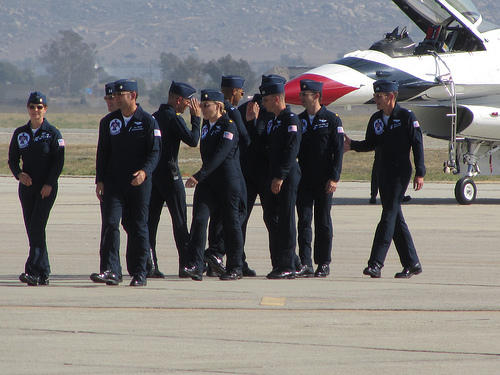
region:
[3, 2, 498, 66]
hazy over rocky terrain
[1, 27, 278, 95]
trees in the distance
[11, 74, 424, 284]
military personnel in uniform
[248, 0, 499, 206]
military plane on tarmac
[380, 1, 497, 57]
open dome on cockpit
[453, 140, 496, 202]
wheel of landing gear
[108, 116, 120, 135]
emblem on front of uniform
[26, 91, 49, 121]
uniform cap on head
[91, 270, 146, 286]
shiny shoes on feet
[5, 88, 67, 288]
an air force officer in uniform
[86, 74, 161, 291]
an air force officer in uniform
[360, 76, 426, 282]
an air force officer in uniform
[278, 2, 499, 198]
a red, black, and white jet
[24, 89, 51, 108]
a blue hat on a person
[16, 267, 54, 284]
black shoes on a woman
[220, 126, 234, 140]
an american flag patch on a uniform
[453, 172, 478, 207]
a black landing tire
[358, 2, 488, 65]
a jet cockpit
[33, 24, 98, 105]
a large tree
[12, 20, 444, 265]
PEOPLE ARE DRESSED IN POLICE CLOTHES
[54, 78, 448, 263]
the people have the same outfit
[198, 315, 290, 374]
the floor is gray in color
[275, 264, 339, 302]
shoies are black incolor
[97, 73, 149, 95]
caps are darkblue in color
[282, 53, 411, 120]
the plan nose has a logo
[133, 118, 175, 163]
the swetaer hand has a logo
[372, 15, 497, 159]
the plane is t a stand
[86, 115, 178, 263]
th dresses are dark bllue in color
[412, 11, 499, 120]
the plane is white incolor